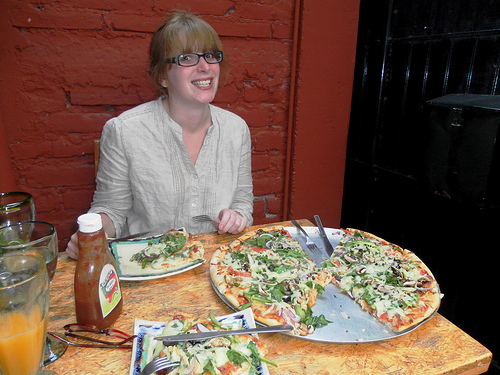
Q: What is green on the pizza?
A: Vegetables.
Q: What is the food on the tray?
A: Pizza.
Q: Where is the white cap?
A: Bottle.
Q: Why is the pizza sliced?
A: To serve.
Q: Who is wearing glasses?
A: Woman At table.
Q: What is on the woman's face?
A: Glasses.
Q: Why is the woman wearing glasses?
A: Poor eyesight.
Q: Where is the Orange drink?
A: Glass on left front.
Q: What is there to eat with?
A: Utensils.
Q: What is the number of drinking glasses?
A: Three.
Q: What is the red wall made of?
A: Brick.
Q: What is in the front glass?
A: Orange juice.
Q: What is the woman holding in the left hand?
A: Fork.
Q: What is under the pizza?
A: Round silver tray.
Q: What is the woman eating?
A: Pizza.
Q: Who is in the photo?
A: A woman.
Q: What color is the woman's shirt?
A: White.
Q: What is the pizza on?
A: A pan.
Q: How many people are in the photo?
A: One.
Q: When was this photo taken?
A: During a meal.